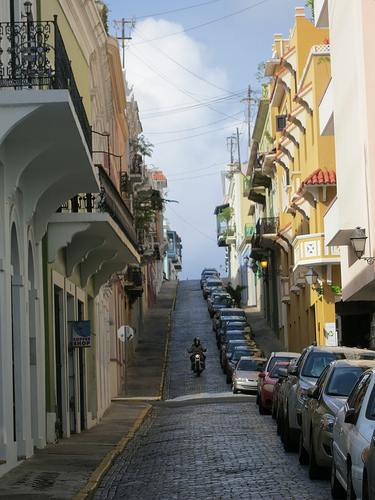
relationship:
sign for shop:
[108, 312, 163, 359] [65, 283, 175, 411]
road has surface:
[137, 265, 232, 345] [168, 338, 196, 366]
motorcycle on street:
[186, 336, 209, 375] [128, 279, 259, 496]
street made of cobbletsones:
[128, 279, 259, 496] [191, 460, 278, 492]